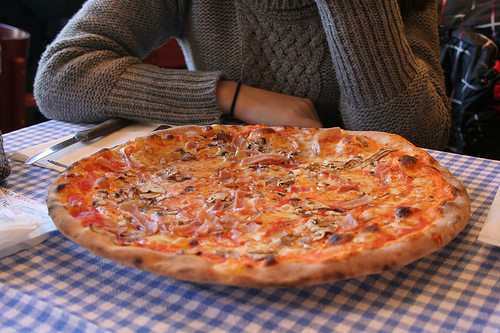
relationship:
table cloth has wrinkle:
[2, 119, 499, 330] [0, 281, 110, 331]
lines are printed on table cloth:
[193, 287, 263, 332] [0, 119, 499, 332]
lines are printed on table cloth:
[63, 270, 168, 330] [0, 119, 499, 332]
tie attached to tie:
[221, 78, 245, 120] [228, 82, 243, 120]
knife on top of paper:
[3, 104, 133, 169] [13, 122, 178, 172]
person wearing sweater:
[33, 0, 451, 151] [27, 4, 426, 134]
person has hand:
[22, 2, 463, 151] [232, 82, 324, 132]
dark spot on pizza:
[65, 173, 78, 180] [40, 121, 466, 281]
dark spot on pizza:
[73, 160, 82, 170] [40, 121, 466, 281]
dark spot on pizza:
[266, 256, 278, 266] [40, 121, 466, 281]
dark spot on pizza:
[194, 245, 204, 260] [40, 121, 466, 281]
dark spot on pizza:
[397, 207, 411, 217] [40, 121, 466, 281]